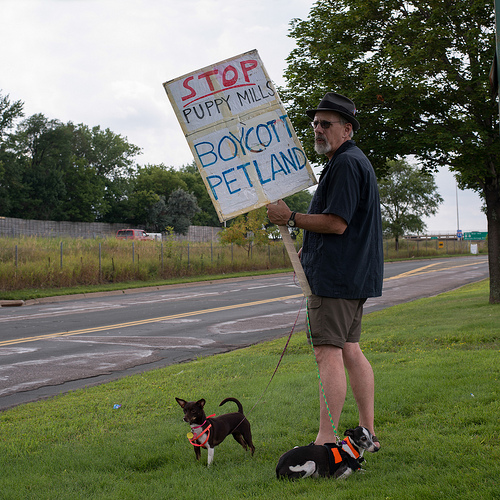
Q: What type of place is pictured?
A: It is a road.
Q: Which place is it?
A: It is a road.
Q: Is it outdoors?
A: Yes, it is outdoors.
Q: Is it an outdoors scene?
A: Yes, it is outdoors.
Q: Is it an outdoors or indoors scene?
A: It is outdoors.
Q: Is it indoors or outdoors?
A: It is outdoors.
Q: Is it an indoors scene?
A: No, it is outdoors.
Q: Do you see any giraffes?
A: No, there are no giraffes.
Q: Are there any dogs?
A: Yes, there is a dog.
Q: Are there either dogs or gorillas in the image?
A: Yes, there is a dog.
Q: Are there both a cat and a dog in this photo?
A: No, there is a dog but no cats.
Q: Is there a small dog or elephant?
A: Yes, there is a small dog.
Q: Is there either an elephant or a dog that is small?
A: Yes, the dog is small.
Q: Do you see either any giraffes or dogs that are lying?
A: Yes, the dog is lying.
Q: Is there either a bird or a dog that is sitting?
A: Yes, the dog is sitting.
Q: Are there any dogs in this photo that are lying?
A: Yes, there is a dog that is lying.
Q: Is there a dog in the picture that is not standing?
A: Yes, there is a dog that is lying.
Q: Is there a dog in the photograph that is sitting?
A: Yes, there is a dog that is sitting.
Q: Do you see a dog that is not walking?
A: Yes, there is a dog that is sitting .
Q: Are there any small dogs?
A: Yes, there is a small dog.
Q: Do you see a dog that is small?
A: Yes, there is a dog that is small.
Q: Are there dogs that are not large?
A: Yes, there is a small dog.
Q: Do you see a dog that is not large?
A: Yes, there is a small dog.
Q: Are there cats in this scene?
A: No, there are no cats.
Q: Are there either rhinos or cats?
A: No, there are no cats or rhinos.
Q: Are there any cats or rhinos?
A: No, there are no cats or rhinos.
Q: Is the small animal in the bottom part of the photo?
A: Yes, the dog is in the bottom of the image.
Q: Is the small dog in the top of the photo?
A: No, the dog is in the bottom of the image.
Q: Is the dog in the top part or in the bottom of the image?
A: The dog is in the bottom of the image.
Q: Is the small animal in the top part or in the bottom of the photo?
A: The dog is in the bottom of the image.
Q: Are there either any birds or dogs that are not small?
A: No, there is a dog but it is small.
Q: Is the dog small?
A: Yes, the dog is small.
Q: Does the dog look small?
A: Yes, the dog is small.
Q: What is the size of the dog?
A: The dog is small.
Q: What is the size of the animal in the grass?
A: The dog is small.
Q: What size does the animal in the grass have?
A: The dog has small size.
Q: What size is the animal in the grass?
A: The dog is small.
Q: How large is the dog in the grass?
A: The dog is small.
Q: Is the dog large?
A: No, the dog is small.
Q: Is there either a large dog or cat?
A: No, there is a dog but it is small.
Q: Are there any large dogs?
A: No, there is a dog but it is small.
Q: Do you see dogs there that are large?
A: No, there is a dog but it is small.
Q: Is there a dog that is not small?
A: No, there is a dog but it is small.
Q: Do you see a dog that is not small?
A: No, there is a dog but it is small.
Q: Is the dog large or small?
A: The dog is small.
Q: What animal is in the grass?
A: The animal is a dog.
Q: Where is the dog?
A: The dog is in the grass.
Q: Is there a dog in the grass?
A: Yes, there is a dog in the grass.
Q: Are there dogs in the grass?
A: Yes, there is a dog in the grass.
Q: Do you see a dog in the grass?
A: Yes, there is a dog in the grass.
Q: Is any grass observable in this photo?
A: Yes, there is grass.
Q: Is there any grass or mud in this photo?
A: Yes, there is grass.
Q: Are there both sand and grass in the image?
A: No, there is grass but no sand.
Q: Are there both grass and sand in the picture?
A: No, there is grass but no sand.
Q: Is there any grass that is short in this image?
A: Yes, there is short grass.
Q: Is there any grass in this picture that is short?
A: Yes, there is grass that is short.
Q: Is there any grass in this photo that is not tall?
A: Yes, there is short grass.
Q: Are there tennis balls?
A: No, there are no tennis balls.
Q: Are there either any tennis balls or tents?
A: No, there are no tennis balls or tents.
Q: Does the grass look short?
A: Yes, the grass is short.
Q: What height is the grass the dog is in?
A: The grass is short.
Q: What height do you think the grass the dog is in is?
A: The grass is short.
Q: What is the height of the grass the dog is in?
A: The grass is short.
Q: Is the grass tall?
A: No, the grass is short.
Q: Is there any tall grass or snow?
A: No, there is grass but it is short.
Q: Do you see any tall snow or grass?
A: No, there is grass but it is short.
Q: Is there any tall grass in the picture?
A: No, there is grass but it is short.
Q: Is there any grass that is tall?
A: No, there is grass but it is short.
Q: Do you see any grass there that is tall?
A: No, there is grass but it is short.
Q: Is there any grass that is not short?
A: No, there is grass but it is short.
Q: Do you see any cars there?
A: No, there are no cars.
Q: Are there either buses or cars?
A: No, there are no cars or buses.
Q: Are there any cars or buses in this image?
A: No, there are no cars or buses.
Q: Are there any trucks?
A: Yes, there is a truck.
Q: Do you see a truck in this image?
A: Yes, there is a truck.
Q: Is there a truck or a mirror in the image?
A: Yes, there is a truck.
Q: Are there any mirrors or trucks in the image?
A: Yes, there is a truck.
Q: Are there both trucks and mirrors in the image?
A: No, there is a truck but no mirrors.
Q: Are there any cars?
A: No, there are no cars.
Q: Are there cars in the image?
A: No, there are no cars.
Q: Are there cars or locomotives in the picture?
A: No, there are no cars or locomotives.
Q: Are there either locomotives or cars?
A: No, there are no cars or locomotives.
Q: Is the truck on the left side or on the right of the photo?
A: The truck is on the left of the image.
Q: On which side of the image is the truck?
A: The truck is on the left of the image.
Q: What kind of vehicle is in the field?
A: The vehicle is a truck.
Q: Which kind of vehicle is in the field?
A: The vehicle is a truck.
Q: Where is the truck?
A: The truck is in the field.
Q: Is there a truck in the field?
A: Yes, there is a truck in the field.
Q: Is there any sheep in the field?
A: No, there is a truck in the field.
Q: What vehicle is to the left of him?
A: The vehicle is a truck.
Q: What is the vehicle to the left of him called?
A: The vehicle is a truck.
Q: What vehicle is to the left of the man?
A: The vehicle is a truck.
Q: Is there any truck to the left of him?
A: Yes, there is a truck to the left of the man.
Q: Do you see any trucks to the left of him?
A: Yes, there is a truck to the left of the man.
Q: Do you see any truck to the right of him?
A: No, the truck is to the left of the man.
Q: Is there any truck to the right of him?
A: No, the truck is to the left of the man.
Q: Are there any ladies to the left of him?
A: No, there is a truck to the left of the man.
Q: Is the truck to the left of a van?
A: No, the truck is to the left of the man.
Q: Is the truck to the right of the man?
A: No, the truck is to the left of the man.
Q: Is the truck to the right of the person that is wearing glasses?
A: No, the truck is to the left of the man.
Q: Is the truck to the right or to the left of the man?
A: The truck is to the left of the man.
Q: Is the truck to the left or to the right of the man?
A: The truck is to the left of the man.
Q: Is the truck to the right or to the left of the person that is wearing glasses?
A: The truck is to the left of the man.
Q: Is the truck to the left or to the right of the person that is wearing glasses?
A: The truck is to the left of the man.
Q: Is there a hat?
A: Yes, there is a hat.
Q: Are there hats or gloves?
A: Yes, there is a hat.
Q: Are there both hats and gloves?
A: No, there is a hat but no gloves.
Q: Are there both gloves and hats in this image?
A: No, there is a hat but no gloves.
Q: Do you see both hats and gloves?
A: No, there is a hat but no gloves.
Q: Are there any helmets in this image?
A: No, there are no helmets.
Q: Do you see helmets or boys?
A: No, there are no helmets or boys.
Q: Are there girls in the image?
A: No, there are no girls.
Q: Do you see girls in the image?
A: No, there are no girls.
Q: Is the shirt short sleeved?
A: Yes, the shirt is short sleeved.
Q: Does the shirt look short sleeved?
A: Yes, the shirt is short sleeved.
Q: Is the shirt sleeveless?
A: No, the shirt is short sleeved.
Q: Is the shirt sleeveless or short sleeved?
A: The shirt is short sleeved.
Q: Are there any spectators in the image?
A: No, there are no spectators.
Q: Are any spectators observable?
A: No, there are no spectators.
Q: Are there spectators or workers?
A: No, there are no spectators or workers.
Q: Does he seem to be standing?
A: Yes, the man is standing.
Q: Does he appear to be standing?
A: Yes, the man is standing.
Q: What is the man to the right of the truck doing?
A: The man is standing.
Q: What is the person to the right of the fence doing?
A: The man is standing.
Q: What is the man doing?
A: The man is standing.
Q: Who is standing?
A: The man is standing.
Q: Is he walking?
A: No, the man is standing.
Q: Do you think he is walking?
A: No, the man is standing.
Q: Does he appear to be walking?
A: No, the man is standing.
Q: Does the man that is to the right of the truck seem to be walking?
A: No, the man is standing.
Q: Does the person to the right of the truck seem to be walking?
A: No, the man is standing.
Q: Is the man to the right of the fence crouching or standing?
A: The man is standing.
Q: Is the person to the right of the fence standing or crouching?
A: The man is standing.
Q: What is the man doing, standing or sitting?
A: The man is standing.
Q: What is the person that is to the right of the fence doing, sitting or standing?
A: The man is standing.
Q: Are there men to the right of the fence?
A: Yes, there is a man to the right of the fence.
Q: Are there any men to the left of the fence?
A: No, the man is to the right of the fence.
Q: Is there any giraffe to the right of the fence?
A: No, there is a man to the right of the fence.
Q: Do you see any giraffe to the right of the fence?
A: No, there is a man to the right of the fence.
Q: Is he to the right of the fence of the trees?
A: Yes, the man is to the right of the fence.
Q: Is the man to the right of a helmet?
A: No, the man is to the right of the fence.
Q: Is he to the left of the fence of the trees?
A: No, the man is to the right of the fence.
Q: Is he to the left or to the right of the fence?
A: The man is to the right of the fence.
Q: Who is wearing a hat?
A: The man is wearing a hat.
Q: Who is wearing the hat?
A: The man is wearing a hat.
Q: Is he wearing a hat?
A: Yes, the man is wearing a hat.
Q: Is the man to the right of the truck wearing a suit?
A: No, the man is wearing a hat.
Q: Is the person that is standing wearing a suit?
A: No, the man is wearing a hat.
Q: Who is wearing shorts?
A: The man is wearing shorts.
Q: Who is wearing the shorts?
A: The man is wearing shorts.